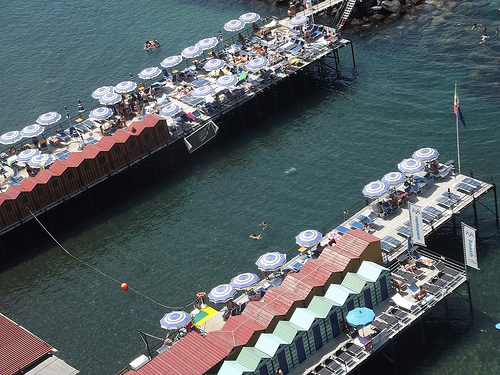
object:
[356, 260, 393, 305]
cabanas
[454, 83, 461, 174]
pole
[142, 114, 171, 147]
huts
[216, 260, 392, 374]
structures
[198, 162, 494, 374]
deck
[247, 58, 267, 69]
umbrella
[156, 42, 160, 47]
person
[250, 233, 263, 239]
people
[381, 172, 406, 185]
umbrella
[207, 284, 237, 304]
umbrella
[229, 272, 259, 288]
umbrella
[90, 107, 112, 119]
umbrella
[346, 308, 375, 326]
umbrella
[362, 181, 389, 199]
umbrella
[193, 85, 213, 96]
umbrella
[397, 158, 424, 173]
umbrella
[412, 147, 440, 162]
umbrella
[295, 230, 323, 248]
umbrella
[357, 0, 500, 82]
bay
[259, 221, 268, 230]
person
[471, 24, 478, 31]
person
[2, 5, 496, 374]
water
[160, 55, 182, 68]
umbrella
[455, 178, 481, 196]
lounges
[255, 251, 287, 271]
umbrella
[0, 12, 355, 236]
dock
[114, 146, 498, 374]
dock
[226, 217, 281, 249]
swimmers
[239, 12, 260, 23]
umbrellas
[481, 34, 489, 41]
people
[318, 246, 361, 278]
storage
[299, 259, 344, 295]
storage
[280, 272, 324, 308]
storage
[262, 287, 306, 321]
storage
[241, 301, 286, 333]
storage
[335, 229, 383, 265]
storage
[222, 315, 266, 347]
storage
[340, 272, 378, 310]
storage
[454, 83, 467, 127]
flag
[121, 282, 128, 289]
ball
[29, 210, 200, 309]
rope